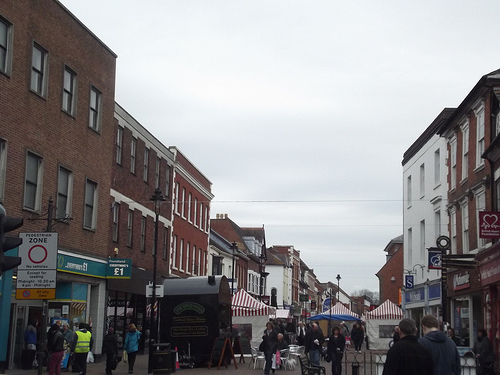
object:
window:
[89, 82, 104, 135]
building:
[2, 0, 119, 372]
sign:
[170, 301, 209, 337]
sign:
[18, 232, 58, 300]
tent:
[231, 288, 276, 358]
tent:
[366, 299, 404, 350]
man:
[71, 323, 94, 375]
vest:
[75, 330, 92, 354]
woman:
[123, 323, 142, 373]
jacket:
[124, 330, 142, 353]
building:
[170, 142, 214, 278]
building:
[397, 107, 446, 336]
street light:
[149, 188, 167, 374]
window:
[379, 325, 400, 339]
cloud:
[210, 75, 324, 113]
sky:
[62, 1, 499, 292]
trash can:
[153, 343, 177, 374]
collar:
[400, 335, 418, 340]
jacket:
[382, 335, 433, 375]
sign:
[208, 337, 238, 370]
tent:
[306, 302, 363, 340]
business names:
[65, 262, 88, 271]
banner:
[57, 250, 109, 279]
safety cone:
[175, 347, 181, 369]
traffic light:
[0, 206, 24, 277]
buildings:
[114, 101, 177, 350]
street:
[173, 339, 370, 374]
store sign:
[453, 271, 471, 291]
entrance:
[450, 296, 472, 351]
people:
[99, 327, 118, 374]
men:
[380, 317, 433, 375]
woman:
[326, 326, 346, 374]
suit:
[327, 334, 346, 374]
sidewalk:
[4, 348, 374, 374]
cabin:
[160, 275, 232, 368]